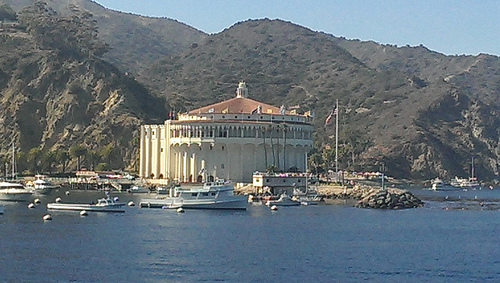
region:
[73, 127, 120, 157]
part of the rocky mountain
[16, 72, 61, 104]
part of the rocky mountain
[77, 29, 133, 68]
part of the rocky mountain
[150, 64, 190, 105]
part of the rocky mountain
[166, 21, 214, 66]
part of the rocky mountain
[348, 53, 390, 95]
part of the rocky mountain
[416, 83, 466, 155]
part of the rocky mountain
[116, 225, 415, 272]
small waves in the blue color water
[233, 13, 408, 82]
mountain with plants and trees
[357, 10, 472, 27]
skies with clouds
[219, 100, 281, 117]
roof of the building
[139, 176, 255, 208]
white color motor boat in the water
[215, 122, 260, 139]
windows of the building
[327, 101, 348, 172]
metal pole near the water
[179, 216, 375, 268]
blue color water with small waves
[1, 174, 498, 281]
a body of water with boats in it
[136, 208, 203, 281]
a reflection on the water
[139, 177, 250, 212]
a boat in the water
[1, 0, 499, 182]
a small mountain behind the water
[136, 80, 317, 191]
a large building on the shore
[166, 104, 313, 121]
a series of flags at the top of the building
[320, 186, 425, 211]
a pile of rocks leading out to the water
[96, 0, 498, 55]
a clear blue sky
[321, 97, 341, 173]
a flag on a flag pole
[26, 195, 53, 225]
buoys in the water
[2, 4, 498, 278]
a scene outside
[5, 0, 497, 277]
a scene during the day time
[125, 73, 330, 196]
a white round building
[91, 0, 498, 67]
a blue sky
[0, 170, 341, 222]
a group of boats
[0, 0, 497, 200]
a hillside in the background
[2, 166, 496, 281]
a blue water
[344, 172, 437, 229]
gray rocks in water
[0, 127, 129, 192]
row of green trees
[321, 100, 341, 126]
this is a flag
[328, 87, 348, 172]
this is a pole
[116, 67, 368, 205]
this is a coliseum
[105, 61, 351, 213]
the coliseum is white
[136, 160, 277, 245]
this is a boat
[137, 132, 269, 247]
the boat is in the water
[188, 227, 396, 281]
the water is blue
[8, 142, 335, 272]
several boats in the water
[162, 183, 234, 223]
a boat in the water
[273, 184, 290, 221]
a boat in the water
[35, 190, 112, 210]
a boat in the water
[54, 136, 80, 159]
green leaves on the tree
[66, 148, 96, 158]
green leaves on the tree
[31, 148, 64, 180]
green leaves on the tree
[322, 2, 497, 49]
a sky that is blue in color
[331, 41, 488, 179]
a mountain that is brown in color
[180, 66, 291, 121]
a roof that is red in color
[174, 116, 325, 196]
a building that is white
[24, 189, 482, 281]
water that is blue in color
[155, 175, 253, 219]
a boat that is white in color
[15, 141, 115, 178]
trees that are green in color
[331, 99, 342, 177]
a pole that is long and grey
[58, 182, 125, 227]
a boat that is white and flat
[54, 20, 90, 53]
green leaves on the tree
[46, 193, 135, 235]
boat in the water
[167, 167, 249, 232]
boat in the water